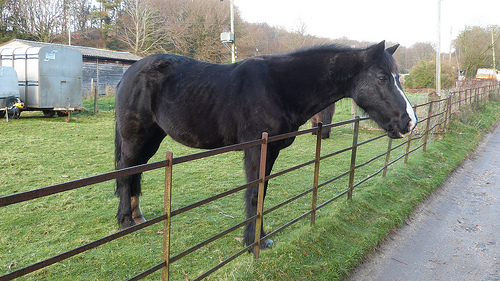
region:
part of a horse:
[185, 103, 212, 132]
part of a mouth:
[386, 110, 418, 146]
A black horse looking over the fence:
[93, 36, 431, 253]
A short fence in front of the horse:
[77, 138, 405, 278]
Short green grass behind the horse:
[4, 125, 99, 170]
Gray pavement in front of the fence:
[422, 199, 491, 264]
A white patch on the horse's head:
[389, 77, 424, 126]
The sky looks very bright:
[310, 7, 402, 33]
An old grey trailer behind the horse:
[18, 45, 88, 119]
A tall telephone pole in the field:
[430, 0, 452, 96]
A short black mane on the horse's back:
[267, 43, 369, 70]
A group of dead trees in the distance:
[87, 0, 217, 52]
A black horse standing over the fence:
[107, 37, 409, 249]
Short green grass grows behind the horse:
[16, 128, 93, 172]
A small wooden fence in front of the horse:
[161, 139, 431, 234]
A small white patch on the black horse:
[390, 73, 420, 123]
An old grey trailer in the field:
[5, 38, 90, 115]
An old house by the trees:
[59, 38, 140, 95]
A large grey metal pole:
[218, 3, 249, 65]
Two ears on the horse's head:
[367, 38, 409, 65]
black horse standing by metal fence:
[108, 35, 416, 251]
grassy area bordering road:
[0, 75, 491, 277]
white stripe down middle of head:
[370, 40, 416, 145]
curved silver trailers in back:
[0, 35, 85, 120]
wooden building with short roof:
[80, 45, 140, 100]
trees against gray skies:
[1, 5, 496, 65]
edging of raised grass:
[242, 97, 492, 277]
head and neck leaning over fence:
[300, 40, 420, 140]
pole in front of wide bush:
[405, 10, 455, 102]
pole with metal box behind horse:
[216, 1, 246, 72]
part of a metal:
[250, 210, 282, 274]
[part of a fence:
[252, 183, 295, 261]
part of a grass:
[341, 193, 358, 227]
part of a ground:
[193, 209, 215, 243]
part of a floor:
[396, 238, 415, 278]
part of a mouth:
[383, 91, 403, 176]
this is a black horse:
[73, 16, 435, 273]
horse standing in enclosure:
[35, 3, 494, 257]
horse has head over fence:
[14, 8, 459, 272]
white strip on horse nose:
[378, 60, 422, 147]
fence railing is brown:
[9, 112, 414, 279]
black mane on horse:
[265, 8, 382, 114]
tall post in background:
[420, 0, 473, 124]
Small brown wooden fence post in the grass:
[147, 145, 182, 276]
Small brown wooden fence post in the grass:
[250, 126, 270, 265]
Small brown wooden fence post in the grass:
[305, 116, 322, 231]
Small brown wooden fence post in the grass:
[348, 103, 365, 198]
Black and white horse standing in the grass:
[85, 17, 436, 267]